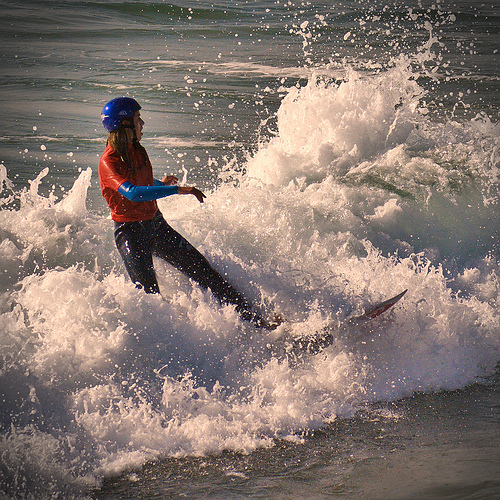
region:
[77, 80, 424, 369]
Woman surfing in the ocean.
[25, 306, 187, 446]
White water from the wave crashing.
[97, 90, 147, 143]
Blue safety helmet on top of the woman's head.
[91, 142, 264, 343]
Woman wearing a wetsuit for warmth.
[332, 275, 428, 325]
Nose of the surfboard coming out of the water.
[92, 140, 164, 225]
Woman wearing a red shirt over the wet suit.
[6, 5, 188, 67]
Green ocean water in the background.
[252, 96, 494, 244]
Wave crashing close to the shore.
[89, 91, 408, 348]
Woman standing on her surfboard.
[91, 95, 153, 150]
Woman with her mouth open.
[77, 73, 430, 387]
Person on a surfboard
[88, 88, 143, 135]
Blue safety helmet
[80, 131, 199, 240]
Orange shirt with blue underneath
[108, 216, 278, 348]
Black wet suit bottoms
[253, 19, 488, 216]
Water splashing in the air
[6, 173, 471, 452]
White foamy water from wave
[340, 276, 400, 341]
Tip of surfboard is white and red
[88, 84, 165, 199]
Person has long hair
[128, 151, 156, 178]
Black lettering on orange shirt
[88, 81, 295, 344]
Surfer wearing orange and black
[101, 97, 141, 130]
a blue safety helmet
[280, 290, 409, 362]
a surfboard in the white water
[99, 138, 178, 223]
an orange a blue wetsuit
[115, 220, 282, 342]
dark wetsuit pants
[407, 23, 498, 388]
white water splash from the wake of a boat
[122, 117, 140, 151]
black straps from a helmet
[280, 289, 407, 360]
a red water ski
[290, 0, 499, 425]
splashing from the wake of a boat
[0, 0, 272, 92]
calm water behind the water skier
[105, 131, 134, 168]
brown hair of the water skier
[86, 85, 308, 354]
surfer in the ocean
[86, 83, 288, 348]
surfer wears a blue helmet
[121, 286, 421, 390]
the nose of surfboard is pointy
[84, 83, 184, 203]
person has long hair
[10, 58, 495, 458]
surfer is in a crushing wave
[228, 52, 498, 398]
crushing wave is white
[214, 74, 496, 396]
crushing wave is foamy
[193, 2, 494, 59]
drops of water in the air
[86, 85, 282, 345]
surfer wears a red tee shirt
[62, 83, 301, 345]
surfer wears a wet pants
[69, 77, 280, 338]
person surfing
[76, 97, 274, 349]
person surfing in ocean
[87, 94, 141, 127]
surfer wearing blue helmet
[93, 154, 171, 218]
surfer wearing blue and orange shirts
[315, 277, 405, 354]
board used by surfer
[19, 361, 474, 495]
white and gray waves in ocean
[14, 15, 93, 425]
white and gray waves in ocean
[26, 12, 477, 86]
white and gray waves in ocean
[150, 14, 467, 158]
white and gray waves in ocean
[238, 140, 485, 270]
white and gray waves in ocean